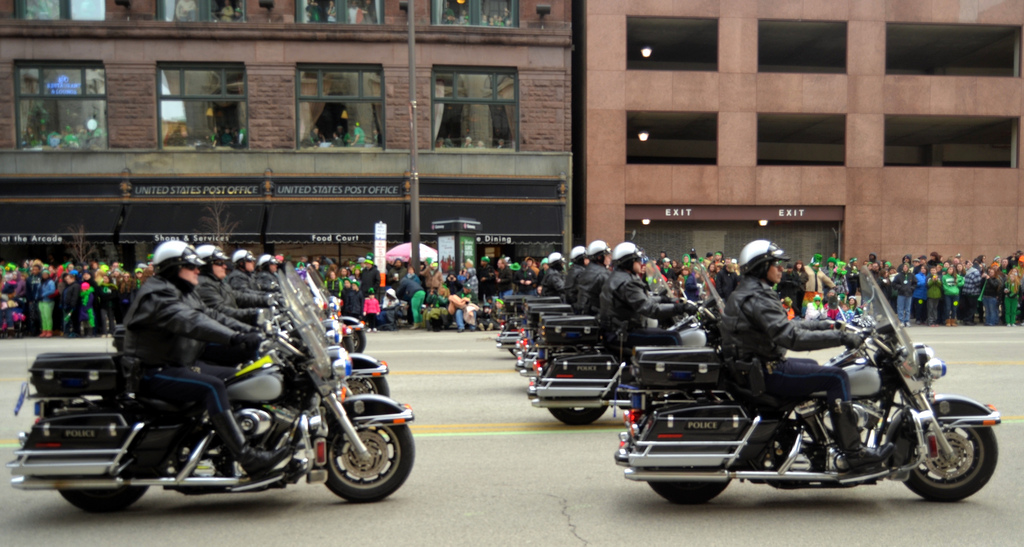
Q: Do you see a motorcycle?
A: Yes, there is a motorcycle.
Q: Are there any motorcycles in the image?
A: Yes, there is a motorcycle.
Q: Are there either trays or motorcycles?
A: Yes, there is a motorcycle.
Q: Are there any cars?
A: No, there are no cars.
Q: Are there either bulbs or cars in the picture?
A: No, there are no cars or bulbs.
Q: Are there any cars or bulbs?
A: No, there are no cars or bulbs.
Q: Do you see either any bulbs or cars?
A: No, there are no cars or bulbs.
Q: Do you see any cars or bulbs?
A: No, there are no cars or bulbs.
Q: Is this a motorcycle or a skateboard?
A: This is a motorcycle.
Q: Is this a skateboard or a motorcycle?
A: This is a motorcycle.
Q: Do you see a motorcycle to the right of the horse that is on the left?
A: Yes, there is a motorcycle to the right of the horse.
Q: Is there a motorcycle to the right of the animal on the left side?
A: Yes, there is a motorcycle to the right of the horse.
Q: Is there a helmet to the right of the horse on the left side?
A: No, there is a motorcycle to the right of the horse.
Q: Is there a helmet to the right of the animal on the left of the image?
A: No, there is a motorcycle to the right of the horse.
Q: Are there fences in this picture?
A: No, there are no fences.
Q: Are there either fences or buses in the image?
A: No, there are no fences or buses.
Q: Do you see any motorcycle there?
A: Yes, there is a motorcycle.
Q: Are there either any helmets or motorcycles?
A: Yes, there is a motorcycle.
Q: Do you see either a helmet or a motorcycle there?
A: Yes, there is a motorcycle.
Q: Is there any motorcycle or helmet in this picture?
A: Yes, there is a motorcycle.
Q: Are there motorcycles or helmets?
A: Yes, there is a motorcycle.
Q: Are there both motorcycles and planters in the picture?
A: No, there is a motorcycle but no planters.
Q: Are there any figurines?
A: No, there are no figurines.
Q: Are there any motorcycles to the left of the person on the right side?
A: Yes, there is a motorcycle to the left of the person.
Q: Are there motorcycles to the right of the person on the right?
A: No, the motorcycle is to the left of the person.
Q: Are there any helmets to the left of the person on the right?
A: No, there is a motorcycle to the left of the person.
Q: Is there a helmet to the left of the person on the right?
A: No, there is a motorcycle to the left of the person.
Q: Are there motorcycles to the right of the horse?
A: Yes, there is a motorcycle to the right of the horse.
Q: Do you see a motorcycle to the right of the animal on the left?
A: Yes, there is a motorcycle to the right of the horse.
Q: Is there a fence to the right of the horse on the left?
A: No, there is a motorcycle to the right of the horse.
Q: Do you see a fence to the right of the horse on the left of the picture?
A: No, there is a motorcycle to the right of the horse.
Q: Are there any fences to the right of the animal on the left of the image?
A: No, there is a motorcycle to the right of the horse.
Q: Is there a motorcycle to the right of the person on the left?
A: Yes, there is a motorcycle to the right of the person.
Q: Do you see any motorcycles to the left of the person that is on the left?
A: No, the motorcycle is to the right of the person.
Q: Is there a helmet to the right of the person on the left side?
A: No, there is a motorcycle to the right of the person.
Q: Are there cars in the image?
A: No, there are no cars.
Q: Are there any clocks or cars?
A: No, there are no cars or clocks.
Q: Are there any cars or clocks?
A: No, there are no cars or clocks.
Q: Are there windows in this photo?
A: Yes, there is a window.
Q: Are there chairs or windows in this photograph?
A: Yes, there is a window.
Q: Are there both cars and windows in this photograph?
A: No, there is a window but no cars.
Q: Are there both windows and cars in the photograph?
A: No, there is a window but no cars.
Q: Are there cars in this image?
A: No, there are no cars.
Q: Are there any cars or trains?
A: No, there are no cars or trains.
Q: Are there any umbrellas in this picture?
A: Yes, there is an umbrella.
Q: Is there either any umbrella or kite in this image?
A: Yes, there is an umbrella.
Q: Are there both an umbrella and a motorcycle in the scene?
A: Yes, there are both an umbrella and a motorcycle.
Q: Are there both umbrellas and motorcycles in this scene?
A: Yes, there are both an umbrella and a motorcycle.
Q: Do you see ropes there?
A: No, there are no ropes.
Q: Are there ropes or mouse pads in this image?
A: No, there are no ropes or mouse pads.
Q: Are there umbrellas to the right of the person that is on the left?
A: Yes, there is an umbrella to the right of the person.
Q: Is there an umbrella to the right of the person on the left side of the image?
A: Yes, there is an umbrella to the right of the person.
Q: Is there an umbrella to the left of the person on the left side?
A: No, the umbrella is to the right of the person.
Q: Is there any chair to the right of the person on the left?
A: No, there is an umbrella to the right of the person.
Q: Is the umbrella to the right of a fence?
A: No, the umbrella is to the right of the person.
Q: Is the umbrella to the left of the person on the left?
A: No, the umbrella is to the right of the person.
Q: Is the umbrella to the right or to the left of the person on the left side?
A: The umbrella is to the right of the person.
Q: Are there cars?
A: No, there are no cars.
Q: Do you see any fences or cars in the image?
A: No, there are no cars or fences.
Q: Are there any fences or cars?
A: No, there are no cars or fences.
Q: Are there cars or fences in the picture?
A: No, there are no cars or fences.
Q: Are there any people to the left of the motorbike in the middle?
A: Yes, there is a person to the left of the motorbike.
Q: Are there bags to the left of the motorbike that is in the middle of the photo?
A: No, there is a person to the left of the motorcycle.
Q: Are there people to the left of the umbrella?
A: Yes, there is a person to the left of the umbrella.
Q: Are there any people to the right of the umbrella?
A: No, the person is to the left of the umbrella.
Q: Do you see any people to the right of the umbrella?
A: No, the person is to the left of the umbrella.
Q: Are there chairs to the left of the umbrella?
A: No, there is a person to the left of the umbrella.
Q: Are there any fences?
A: No, there are no fences.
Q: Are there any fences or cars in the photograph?
A: No, there are no fences or cars.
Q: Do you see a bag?
A: No, there are no bags.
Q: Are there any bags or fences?
A: No, there are no bags or fences.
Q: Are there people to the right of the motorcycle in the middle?
A: Yes, there is a person to the right of the motorbike.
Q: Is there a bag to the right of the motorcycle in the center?
A: No, there is a person to the right of the motorcycle.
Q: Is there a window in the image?
A: Yes, there is a window.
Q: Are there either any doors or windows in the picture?
A: Yes, there is a window.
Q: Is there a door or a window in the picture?
A: Yes, there is a window.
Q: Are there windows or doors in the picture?
A: Yes, there is a window.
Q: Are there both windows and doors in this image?
A: No, there is a window but no doors.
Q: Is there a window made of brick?
A: Yes, there is a window that is made of brick.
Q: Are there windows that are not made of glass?
A: Yes, there is a window that is made of brick.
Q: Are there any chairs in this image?
A: No, there are no chairs.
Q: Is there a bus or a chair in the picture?
A: No, there are no chairs or buses.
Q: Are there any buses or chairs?
A: No, there are no chairs or buses.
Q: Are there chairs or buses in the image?
A: No, there are no chairs or buses.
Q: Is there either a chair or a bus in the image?
A: No, there are no chairs or buses.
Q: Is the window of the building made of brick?
A: Yes, the window is made of brick.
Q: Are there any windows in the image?
A: Yes, there is a window.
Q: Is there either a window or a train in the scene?
A: Yes, there is a window.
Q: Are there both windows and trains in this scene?
A: No, there is a window but no trains.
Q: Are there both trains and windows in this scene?
A: No, there is a window but no trains.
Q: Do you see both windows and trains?
A: No, there is a window but no trains.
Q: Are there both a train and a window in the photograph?
A: No, there is a window but no trains.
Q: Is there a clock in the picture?
A: No, there are no clocks.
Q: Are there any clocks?
A: No, there are no clocks.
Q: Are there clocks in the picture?
A: No, there are no clocks.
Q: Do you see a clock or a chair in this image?
A: No, there are no clocks or chairs.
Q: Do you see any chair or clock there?
A: No, there are no clocks or chairs.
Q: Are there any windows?
A: Yes, there is a window.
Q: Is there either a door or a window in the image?
A: Yes, there is a window.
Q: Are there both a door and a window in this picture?
A: No, there is a window but no doors.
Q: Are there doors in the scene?
A: No, there are no doors.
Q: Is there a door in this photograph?
A: No, there are no doors.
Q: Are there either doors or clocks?
A: No, there are no doors or clocks.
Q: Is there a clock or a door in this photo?
A: No, there are no doors or clocks.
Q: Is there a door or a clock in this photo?
A: No, there are no doors or clocks.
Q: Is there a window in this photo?
A: Yes, there is a window.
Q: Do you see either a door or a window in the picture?
A: Yes, there is a window.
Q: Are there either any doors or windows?
A: Yes, there is a window.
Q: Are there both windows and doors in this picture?
A: No, there is a window but no doors.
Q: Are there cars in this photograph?
A: No, there are no cars.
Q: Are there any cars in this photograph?
A: No, there are no cars.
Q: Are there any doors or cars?
A: No, there are no cars or doors.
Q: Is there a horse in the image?
A: Yes, there is a horse.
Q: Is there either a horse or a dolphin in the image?
A: Yes, there is a horse.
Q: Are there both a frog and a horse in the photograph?
A: No, there is a horse but no frogs.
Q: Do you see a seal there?
A: No, there are no seals.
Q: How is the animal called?
A: The animal is a horse.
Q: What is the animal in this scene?
A: The animal is a horse.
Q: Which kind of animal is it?
A: The animal is a horse.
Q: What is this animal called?
A: This is a horse.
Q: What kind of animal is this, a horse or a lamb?
A: This is a horse.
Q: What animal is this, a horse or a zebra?
A: This is a horse.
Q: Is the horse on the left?
A: Yes, the horse is on the left of the image.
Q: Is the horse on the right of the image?
A: No, the horse is on the left of the image.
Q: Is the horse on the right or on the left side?
A: The horse is on the left of the image.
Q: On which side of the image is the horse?
A: The horse is on the left of the image.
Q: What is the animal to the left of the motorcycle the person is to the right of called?
A: The animal is a horse.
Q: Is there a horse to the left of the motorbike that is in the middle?
A: Yes, there is a horse to the left of the motorcycle.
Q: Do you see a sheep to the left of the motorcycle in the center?
A: No, there is a horse to the left of the motorcycle.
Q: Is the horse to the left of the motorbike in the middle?
A: Yes, the horse is to the left of the motorcycle.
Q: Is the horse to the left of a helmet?
A: No, the horse is to the left of the motorcycle.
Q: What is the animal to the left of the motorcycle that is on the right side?
A: The animal is a horse.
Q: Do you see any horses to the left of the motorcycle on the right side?
A: Yes, there is a horse to the left of the motorcycle.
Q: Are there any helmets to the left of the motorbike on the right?
A: No, there is a horse to the left of the motorbike.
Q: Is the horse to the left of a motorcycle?
A: Yes, the horse is to the left of a motorcycle.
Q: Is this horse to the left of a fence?
A: No, the horse is to the left of a motorcycle.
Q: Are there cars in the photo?
A: No, there are no cars.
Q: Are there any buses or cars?
A: No, there are no cars or buses.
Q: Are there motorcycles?
A: Yes, there is a motorcycle.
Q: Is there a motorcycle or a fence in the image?
A: Yes, there is a motorcycle.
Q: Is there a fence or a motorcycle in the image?
A: Yes, there is a motorcycle.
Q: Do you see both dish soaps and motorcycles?
A: No, there is a motorcycle but no dish soaps.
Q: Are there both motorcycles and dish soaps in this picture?
A: No, there is a motorcycle but no dish soaps.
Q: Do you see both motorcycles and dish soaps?
A: No, there is a motorcycle but no dish soaps.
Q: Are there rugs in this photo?
A: No, there are no rugs.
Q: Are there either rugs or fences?
A: No, there are no rugs or fences.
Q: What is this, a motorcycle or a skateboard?
A: This is a motorcycle.